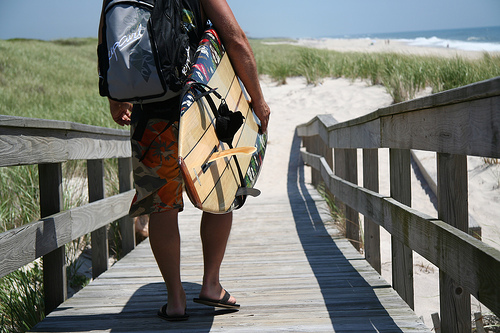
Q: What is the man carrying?
A: Surfboard.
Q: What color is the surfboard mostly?
A: White.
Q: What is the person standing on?
A: Bridge.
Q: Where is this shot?
A: Beach.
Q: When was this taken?
A: Daytime.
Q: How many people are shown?
A: 1.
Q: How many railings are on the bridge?
A: 2.